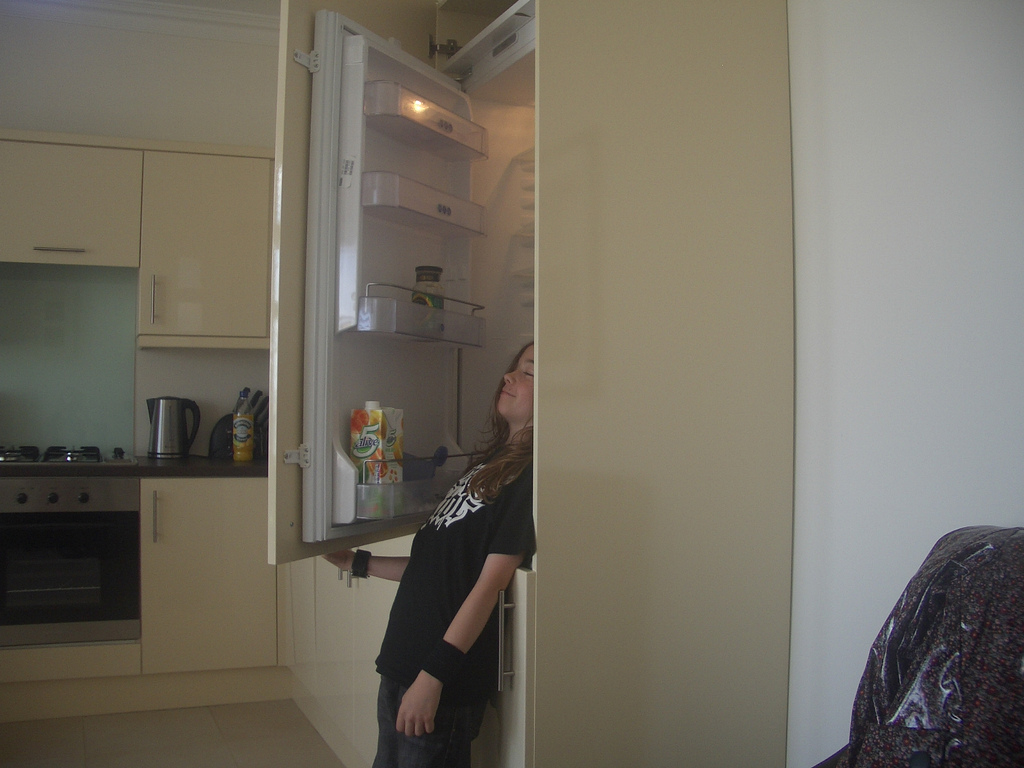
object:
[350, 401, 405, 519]
juice container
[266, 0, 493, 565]
fridge door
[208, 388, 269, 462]
knife block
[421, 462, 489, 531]
logo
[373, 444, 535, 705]
shirt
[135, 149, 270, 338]
cabinet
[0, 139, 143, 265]
cabinet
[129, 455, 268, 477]
countertop